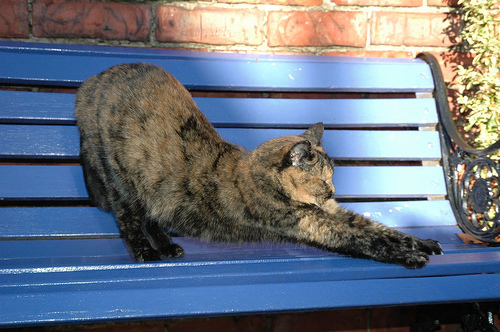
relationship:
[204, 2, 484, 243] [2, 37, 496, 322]
sun shining bench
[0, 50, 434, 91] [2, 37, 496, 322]
panel of bench